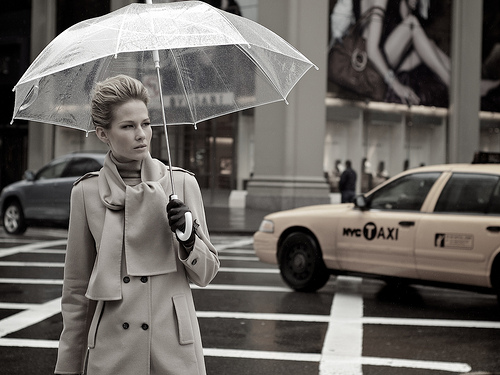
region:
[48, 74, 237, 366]
A woman in the photo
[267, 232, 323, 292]
Wheel of a car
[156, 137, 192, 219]
A handle of an umbrella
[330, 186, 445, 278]
A car on the road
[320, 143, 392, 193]
People on the street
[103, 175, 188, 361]
A coat in the photo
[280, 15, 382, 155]
A building in the photo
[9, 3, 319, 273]
a woman carrying an umbrella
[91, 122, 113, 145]
the ear of a woman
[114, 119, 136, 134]
the eye of a woman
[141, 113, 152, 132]
the eye of a woman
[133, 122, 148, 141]
the nose of a woman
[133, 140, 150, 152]
the mouth of a woman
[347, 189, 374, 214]
a rear view mirror of a car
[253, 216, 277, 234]
the head light of a car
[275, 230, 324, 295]
the wheel of a car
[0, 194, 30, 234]
the wheel of a car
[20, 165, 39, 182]
the rear view mirror of a car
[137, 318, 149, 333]
a button on a coat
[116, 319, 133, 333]
a button on a coat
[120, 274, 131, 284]
a button on a coat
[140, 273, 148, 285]
a button on a coat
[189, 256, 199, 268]
a button on a coat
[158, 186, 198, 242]
a glove hand holding onto an umbrella handle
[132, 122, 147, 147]
the nose of a woman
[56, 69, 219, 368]
this is a person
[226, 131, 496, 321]
this is a car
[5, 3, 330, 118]
this is an umbrella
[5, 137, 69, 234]
this is a car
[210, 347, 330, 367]
a line on the road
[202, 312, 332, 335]
a line on the road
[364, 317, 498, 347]
a line on the road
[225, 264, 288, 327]
a line on the road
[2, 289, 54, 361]
a line on the road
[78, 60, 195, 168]
the head of a woman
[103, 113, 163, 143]
the eyes of a woman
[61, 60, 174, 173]
the hair of a woman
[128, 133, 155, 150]
the nose of a woman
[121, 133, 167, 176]
the lips of a woman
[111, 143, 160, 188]
the lips of a woman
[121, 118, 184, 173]
the mouth of a woman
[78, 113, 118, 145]
the ear of a woman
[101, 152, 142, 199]
the neck of a woman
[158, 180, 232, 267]
the hand of a woman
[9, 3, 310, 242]
The woman is holding a white umbrella.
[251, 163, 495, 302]
The taxi is crossing over the crosswalk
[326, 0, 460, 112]
There is a large picture on the building.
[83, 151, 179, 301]
The woman is wearing a nuetral colored scarf.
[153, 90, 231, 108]
There is writing on the building.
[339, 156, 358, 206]
A person is standing up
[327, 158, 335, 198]
A person is standing up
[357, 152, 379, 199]
A person is standing up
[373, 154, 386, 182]
A person is standing up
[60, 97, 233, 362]
A person is standing up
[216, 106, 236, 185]
A window on a building.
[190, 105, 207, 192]
A window on a building.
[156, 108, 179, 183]
A window on a building.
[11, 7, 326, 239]
a large open umbrella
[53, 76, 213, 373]
a person is standing up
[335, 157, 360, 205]
a person is standing up